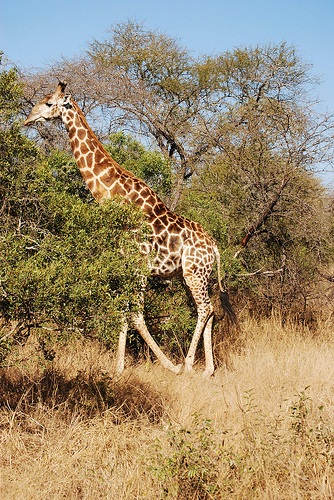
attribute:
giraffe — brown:
[20, 63, 239, 410]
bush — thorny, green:
[0, 152, 199, 392]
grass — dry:
[11, 374, 331, 498]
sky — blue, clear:
[210, 6, 290, 34]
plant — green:
[162, 423, 201, 498]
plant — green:
[240, 386, 265, 498]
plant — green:
[291, 383, 310, 451]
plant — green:
[191, 410, 218, 454]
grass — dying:
[4, 273, 327, 496]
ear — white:
[59, 90, 71, 106]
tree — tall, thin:
[28, 24, 332, 347]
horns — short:
[54, 77, 74, 93]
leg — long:
[183, 276, 208, 375]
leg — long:
[203, 313, 215, 378]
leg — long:
[133, 281, 180, 378]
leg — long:
[118, 325, 128, 370]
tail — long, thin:
[209, 236, 237, 319]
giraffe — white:
[27, 89, 230, 326]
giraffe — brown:
[38, 85, 245, 330]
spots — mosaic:
[134, 199, 154, 214]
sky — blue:
[32, 17, 324, 167]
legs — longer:
[105, 256, 186, 379]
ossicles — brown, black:
[54, 76, 69, 102]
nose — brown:
[13, 104, 50, 129]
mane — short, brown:
[71, 104, 146, 192]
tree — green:
[0, 52, 158, 375]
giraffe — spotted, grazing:
[24, 79, 240, 380]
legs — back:
[182, 249, 215, 374]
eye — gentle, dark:
[45, 100, 54, 106]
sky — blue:
[4, 3, 319, 184]